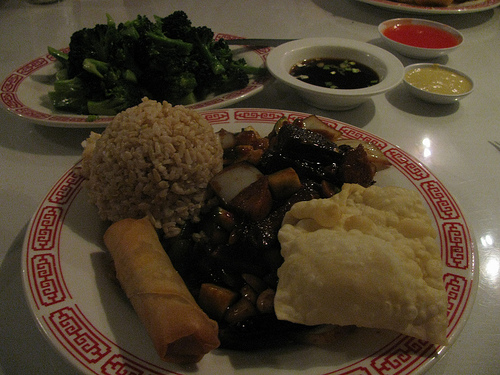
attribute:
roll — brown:
[98, 213, 231, 369]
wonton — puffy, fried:
[285, 188, 447, 333]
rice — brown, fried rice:
[84, 103, 213, 223]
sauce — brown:
[286, 46, 383, 110]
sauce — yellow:
[402, 60, 474, 104]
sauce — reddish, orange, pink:
[382, 16, 460, 58]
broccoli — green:
[59, 21, 226, 99]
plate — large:
[21, 117, 463, 361]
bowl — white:
[402, 60, 476, 108]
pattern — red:
[375, 135, 464, 223]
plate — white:
[8, 29, 242, 120]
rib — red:
[275, 127, 331, 171]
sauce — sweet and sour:
[290, 56, 380, 88]